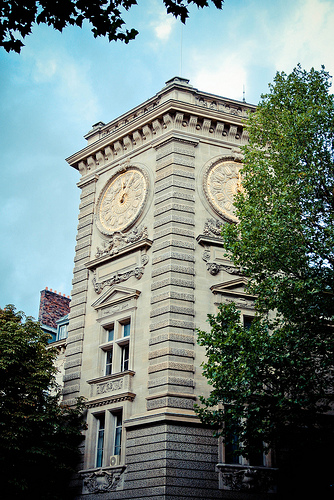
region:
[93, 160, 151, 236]
Clock in the tower.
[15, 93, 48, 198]
Bright blue sky high above.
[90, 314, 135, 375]
Windows in the building.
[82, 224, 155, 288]
Decorations below the clock.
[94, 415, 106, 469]
Blue curtains at the window.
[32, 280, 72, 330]
Stone chimney on the roof.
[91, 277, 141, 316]
Triangle above the window.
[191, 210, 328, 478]
Leafy green tree in front of the building.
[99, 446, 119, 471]
Small fan in the bottom window.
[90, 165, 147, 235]
A clock is on the building.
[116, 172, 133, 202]
The clock reads 12:05.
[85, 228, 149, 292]
A decorative area is below the clock.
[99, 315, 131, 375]
Windows are on the building.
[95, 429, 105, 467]
The window curtain is blue.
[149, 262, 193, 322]
The building is made of stone.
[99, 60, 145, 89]
The sky is blue.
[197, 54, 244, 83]
Clouds are in the sky.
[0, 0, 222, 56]
A tree's leaves hang over the building.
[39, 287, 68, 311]
A chimney is behind the building.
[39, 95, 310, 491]
this is a building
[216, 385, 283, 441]
these are leaves in a branch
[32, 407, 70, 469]
these are leaves in a branch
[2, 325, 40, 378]
these are leaves in a branch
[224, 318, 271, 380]
these are leaves in a branch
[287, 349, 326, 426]
these are leaves in a branch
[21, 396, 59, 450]
these are leaves in a branch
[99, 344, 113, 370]
this is a window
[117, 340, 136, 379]
this is a window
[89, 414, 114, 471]
this is a window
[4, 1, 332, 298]
white clouds in sky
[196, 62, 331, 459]
green leaves on tree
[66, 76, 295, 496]
corner of clock tower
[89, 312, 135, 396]
two windows with balcony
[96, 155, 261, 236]
face of two clocks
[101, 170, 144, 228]
clock with gold hands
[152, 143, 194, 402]
ribbed corner of structure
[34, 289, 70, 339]
square flat chimney on roof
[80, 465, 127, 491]
design element on building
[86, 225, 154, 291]
decorative element under clock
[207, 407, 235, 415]
part of a building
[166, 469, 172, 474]
side of a building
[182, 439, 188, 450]
edge of a wall